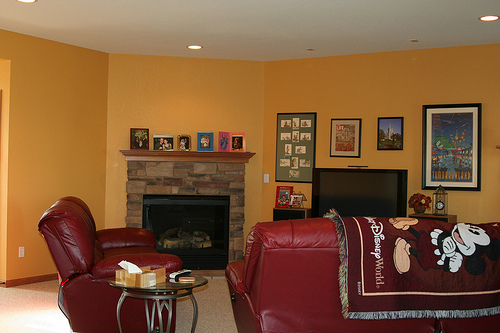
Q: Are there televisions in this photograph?
A: Yes, there is a television.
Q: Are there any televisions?
A: Yes, there is a television.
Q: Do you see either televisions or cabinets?
A: Yes, there is a television.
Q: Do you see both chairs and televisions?
A: Yes, there are both a television and a chair.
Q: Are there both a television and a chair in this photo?
A: Yes, there are both a television and a chair.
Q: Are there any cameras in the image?
A: No, there are no cameras.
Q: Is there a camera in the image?
A: No, there are no cameras.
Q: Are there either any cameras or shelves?
A: No, there are no cameras or shelves.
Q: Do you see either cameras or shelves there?
A: No, there are no cameras or shelves.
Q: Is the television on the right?
A: Yes, the television is on the right of the image.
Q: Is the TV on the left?
A: No, the TV is on the right of the image.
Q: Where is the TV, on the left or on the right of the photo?
A: The TV is on the right of the image.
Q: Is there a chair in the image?
A: Yes, there is a chair.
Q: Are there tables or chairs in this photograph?
A: Yes, there is a chair.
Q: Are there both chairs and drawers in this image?
A: No, there is a chair but no drawers.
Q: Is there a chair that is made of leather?
A: Yes, there is a chair that is made of leather.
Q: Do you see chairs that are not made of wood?
A: Yes, there is a chair that is made of leather.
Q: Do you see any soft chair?
A: Yes, there is a soft chair.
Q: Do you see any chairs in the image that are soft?
A: Yes, there is a chair that is soft.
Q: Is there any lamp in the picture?
A: No, there are no lamps.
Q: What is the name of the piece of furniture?
A: The piece of furniture is a chair.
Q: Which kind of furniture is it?
A: The piece of furniture is a chair.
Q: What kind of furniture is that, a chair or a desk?
A: This is a chair.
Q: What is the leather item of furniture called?
A: The piece of furniture is a chair.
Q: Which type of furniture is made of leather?
A: The furniture is a chair.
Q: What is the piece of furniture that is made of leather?
A: The piece of furniture is a chair.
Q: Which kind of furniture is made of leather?
A: The furniture is a chair.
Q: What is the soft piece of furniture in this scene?
A: The piece of furniture is a chair.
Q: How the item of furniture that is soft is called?
A: The piece of furniture is a chair.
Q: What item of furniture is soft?
A: The piece of furniture is a chair.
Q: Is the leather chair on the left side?
A: Yes, the chair is on the left of the image.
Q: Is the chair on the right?
A: No, the chair is on the left of the image.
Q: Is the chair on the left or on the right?
A: The chair is on the left of the image.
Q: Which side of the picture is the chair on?
A: The chair is on the left of the image.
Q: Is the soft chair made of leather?
A: Yes, the chair is made of leather.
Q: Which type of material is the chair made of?
A: The chair is made of leather.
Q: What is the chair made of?
A: The chair is made of leather.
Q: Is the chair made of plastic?
A: No, the chair is made of leather.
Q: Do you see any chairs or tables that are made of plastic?
A: No, there is a chair but it is made of leather.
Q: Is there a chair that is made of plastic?
A: No, there is a chair but it is made of leather.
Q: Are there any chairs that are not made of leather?
A: No, there is a chair but it is made of leather.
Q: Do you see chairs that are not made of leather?
A: No, there is a chair but it is made of leather.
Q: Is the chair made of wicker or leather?
A: The chair is made of leather.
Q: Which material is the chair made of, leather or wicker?
A: The chair is made of leather.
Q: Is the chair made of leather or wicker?
A: The chair is made of leather.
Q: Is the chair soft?
A: Yes, the chair is soft.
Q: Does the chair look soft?
A: Yes, the chair is soft.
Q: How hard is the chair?
A: The chair is soft.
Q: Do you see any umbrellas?
A: No, there are no umbrellas.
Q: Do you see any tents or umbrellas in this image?
A: No, there are no umbrellas or tents.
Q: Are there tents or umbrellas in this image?
A: No, there are no umbrellas or tents.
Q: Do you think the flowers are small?
A: Yes, the flowers are small.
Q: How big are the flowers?
A: The flowers are small.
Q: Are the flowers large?
A: No, the flowers are small.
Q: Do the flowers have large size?
A: No, the flowers are small.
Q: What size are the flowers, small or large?
A: The flowers are small.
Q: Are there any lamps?
A: No, there are no lamps.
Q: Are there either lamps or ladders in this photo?
A: No, there are no lamps or ladders.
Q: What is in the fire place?
A: The logs are in the fire place.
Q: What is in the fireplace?
A: The logs are in the fire place.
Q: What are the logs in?
A: The logs are in the fireplace.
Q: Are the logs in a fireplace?
A: Yes, the logs are in a fireplace.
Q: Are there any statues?
A: No, there are no statues.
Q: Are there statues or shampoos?
A: No, there are no statues or shampoos.